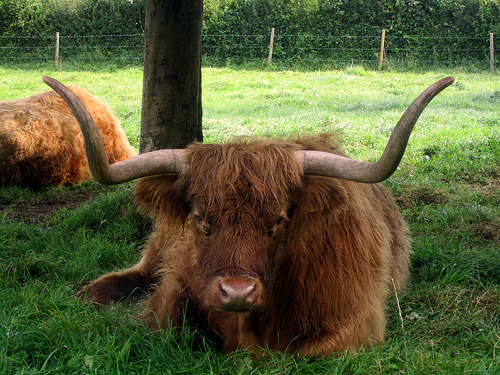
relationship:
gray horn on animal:
[287, 75, 458, 184] [38, 73, 456, 360]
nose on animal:
[215, 275, 263, 306] [38, 73, 456, 360]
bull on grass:
[1, 83, 141, 187] [1, 33, 497, 371]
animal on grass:
[38, 73, 456, 360] [1, 33, 497, 371]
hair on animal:
[105, 140, 405, 352] [38, 73, 456, 360]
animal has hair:
[38, 73, 456, 360] [105, 140, 405, 352]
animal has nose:
[38, 73, 456, 360] [215, 275, 263, 306]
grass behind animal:
[1, 33, 497, 371] [38, 73, 456, 360]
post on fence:
[377, 28, 388, 71] [3, 25, 497, 72]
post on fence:
[264, 26, 279, 68] [3, 25, 497, 72]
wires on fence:
[11, 22, 496, 79] [0, 27, 500, 74]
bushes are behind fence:
[1, 0, 484, 60] [1, 16, 495, 79]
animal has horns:
[44, 62, 414, 326] [27, 67, 451, 188]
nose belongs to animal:
[211, 270, 263, 312] [41, 72, 456, 362]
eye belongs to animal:
[202, 224, 210, 234] [41, 72, 456, 362]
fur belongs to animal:
[319, 223, 387, 294] [41, 72, 456, 362]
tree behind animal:
[137, 2, 204, 153] [48, 65, 415, 354]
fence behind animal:
[270, 23, 398, 70] [38, 73, 456, 360]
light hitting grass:
[226, 85, 374, 138] [1, 33, 497, 371]